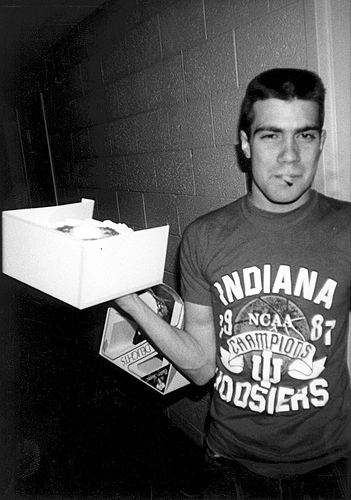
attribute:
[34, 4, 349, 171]
wall — brick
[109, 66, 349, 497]
man — smoking, young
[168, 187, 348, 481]
shirt — grey, man's, tee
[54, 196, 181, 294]
flap — top, opened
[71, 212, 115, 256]
light — icing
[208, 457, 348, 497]
pants — dark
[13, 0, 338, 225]
wall — brick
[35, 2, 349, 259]
wall — cinderblock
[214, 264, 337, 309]
letters — white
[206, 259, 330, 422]
fabric — white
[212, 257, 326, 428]
fabric — white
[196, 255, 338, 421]
fabric — white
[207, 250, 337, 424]
fabric — white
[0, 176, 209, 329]
box — white